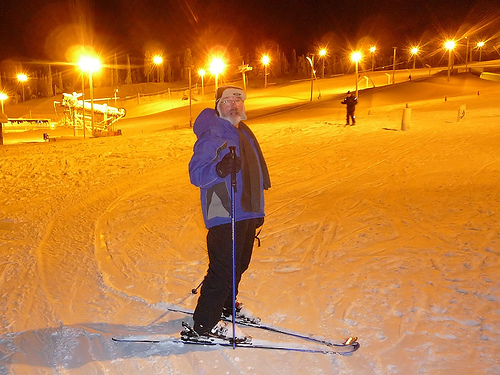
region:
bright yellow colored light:
[74, 50, 104, 77]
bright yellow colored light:
[0, 90, 10, 105]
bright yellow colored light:
[13, 68, 28, 86]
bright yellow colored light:
[149, 50, 164, 64]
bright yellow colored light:
[196, 65, 208, 75]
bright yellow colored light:
[203, 53, 227, 75]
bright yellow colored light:
[258, 50, 272, 67]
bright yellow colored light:
[318, 46, 328, 55]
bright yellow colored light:
[348, 48, 364, 65]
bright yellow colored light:
[409, 43, 419, 57]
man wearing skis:
[107, 80, 372, 350]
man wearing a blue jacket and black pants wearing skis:
[58, 46, 416, 373]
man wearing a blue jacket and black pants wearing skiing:
[116, 41, 406, 372]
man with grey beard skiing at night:
[70, 15, 478, 370]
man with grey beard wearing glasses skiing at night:
[83, 56, 410, 371]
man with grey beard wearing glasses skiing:
[92, 55, 392, 367]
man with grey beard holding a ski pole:
[107, 52, 410, 372]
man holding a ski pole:
[96, 60, 386, 370]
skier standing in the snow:
[91, 62, 412, 372]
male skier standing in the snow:
[66, 71, 410, 373]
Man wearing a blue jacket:
[178, 80, 283, 348]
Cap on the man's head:
[207, 80, 253, 118]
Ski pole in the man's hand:
[212, 140, 247, 350]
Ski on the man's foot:
[107, 323, 354, 374]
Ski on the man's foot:
[155, 288, 369, 348]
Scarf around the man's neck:
[227, 119, 273, 216]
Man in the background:
[330, 83, 363, 132]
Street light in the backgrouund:
[61, 39, 111, 147]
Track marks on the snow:
[25, 157, 172, 354]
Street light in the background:
[342, 43, 372, 100]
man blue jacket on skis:
[115, 59, 368, 372]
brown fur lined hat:
[205, 80, 259, 130]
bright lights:
[57, 35, 114, 80]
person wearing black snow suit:
[335, 82, 362, 132]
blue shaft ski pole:
[222, 144, 255, 358]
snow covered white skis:
[112, 282, 377, 358]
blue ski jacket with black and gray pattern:
[182, 107, 287, 223]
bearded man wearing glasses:
[223, 97, 248, 122]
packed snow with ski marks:
[54, 175, 158, 291]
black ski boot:
[190, 315, 264, 342]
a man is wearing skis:
[125, 85, 360, 357]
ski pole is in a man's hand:
[227, 145, 242, 351]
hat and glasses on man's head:
[212, 85, 246, 129]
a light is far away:
[81, 55, 105, 76]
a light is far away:
[153, 55, 163, 68]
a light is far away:
[208, 54, 228, 78]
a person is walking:
[340, 90, 359, 130]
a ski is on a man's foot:
[110, 335, 359, 357]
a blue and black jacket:
[187, 109, 271, 227]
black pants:
[191, 220, 255, 328]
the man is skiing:
[123, 83, 358, 358]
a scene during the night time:
[21, 35, 493, 370]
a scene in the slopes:
[16, 27, 484, 367]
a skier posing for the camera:
[110, 72, 371, 359]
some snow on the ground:
[14, 112, 498, 357]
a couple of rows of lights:
[13, 25, 498, 115]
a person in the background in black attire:
[88, 76, 373, 368]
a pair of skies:
[108, 292, 373, 372]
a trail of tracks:
[25, 201, 180, 343]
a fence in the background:
[76, 72, 251, 114]